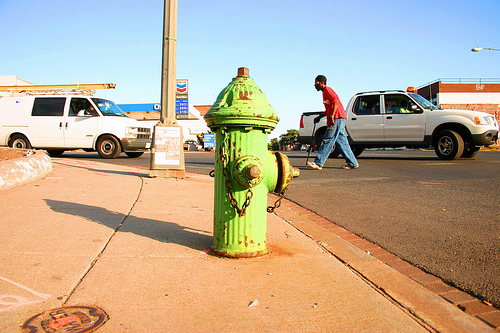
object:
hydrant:
[202, 67, 299, 258]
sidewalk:
[0, 155, 499, 333]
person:
[307, 74, 359, 169]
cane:
[306, 118, 317, 168]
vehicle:
[298, 88, 498, 161]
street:
[0, 150, 499, 312]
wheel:
[434, 130, 463, 160]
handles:
[386, 116, 393, 119]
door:
[383, 94, 425, 142]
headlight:
[474, 116, 493, 125]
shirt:
[319, 86, 347, 126]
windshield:
[407, 93, 440, 109]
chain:
[221, 154, 253, 218]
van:
[0, 83, 151, 158]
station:
[100, 104, 216, 151]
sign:
[175, 79, 188, 119]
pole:
[149, 0, 184, 172]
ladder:
[0, 83, 116, 92]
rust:
[248, 167, 261, 177]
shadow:
[44, 200, 214, 252]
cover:
[18, 304, 112, 332]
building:
[412, 77, 500, 150]